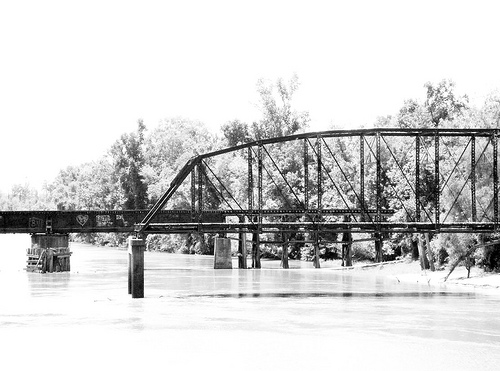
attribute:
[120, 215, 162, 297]
leg — bridge's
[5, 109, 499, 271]
bridge — black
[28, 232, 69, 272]
pillar — cement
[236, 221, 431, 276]
fence — wooden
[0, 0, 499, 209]
sky — clear, white, bright white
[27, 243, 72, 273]
wood pieces — a bunch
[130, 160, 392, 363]
frozen lake/bridge — big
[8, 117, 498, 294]
bridge — white, worn out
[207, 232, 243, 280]
stone — large piece